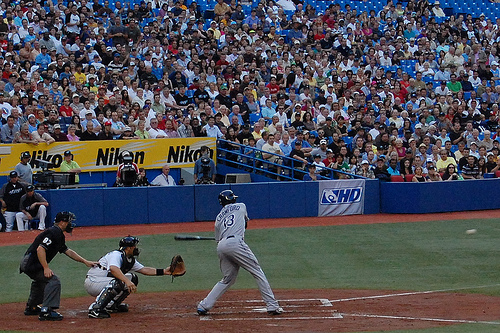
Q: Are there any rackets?
A: No, there are no rackets.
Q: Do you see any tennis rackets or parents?
A: No, there are no tennis rackets or parents.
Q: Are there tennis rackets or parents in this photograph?
A: No, there are no tennis rackets or parents.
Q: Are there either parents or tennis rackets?
A: No, there are no tennis rackets or parents.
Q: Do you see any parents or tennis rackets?
A: No, there are no tennis rackets or parents.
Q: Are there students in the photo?
A: No, there are no students.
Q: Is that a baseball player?
A: Yes, that is a baseball player.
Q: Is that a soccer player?
A: No, that is a baseball player.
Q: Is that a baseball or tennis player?
A: That is a baseball player.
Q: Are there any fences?
A: Yes, there is a fence.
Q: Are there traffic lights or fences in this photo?
A: Yes, there is a fence.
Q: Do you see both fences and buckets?
A: No, there is a fence but no buckets.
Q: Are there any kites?
A: No, there are no kites.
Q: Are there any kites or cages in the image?
A: No, there are no kites or cages.